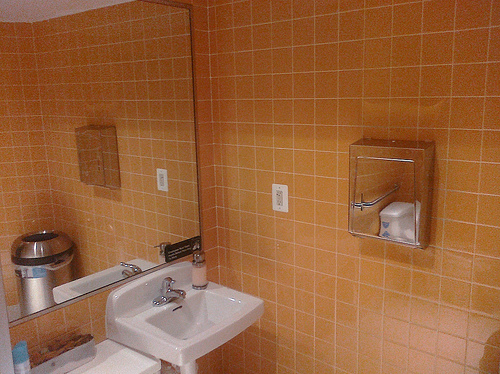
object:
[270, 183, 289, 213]
outlet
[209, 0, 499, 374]
wall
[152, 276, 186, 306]
faucet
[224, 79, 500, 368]
tile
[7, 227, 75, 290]
trash can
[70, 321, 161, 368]
umbrellas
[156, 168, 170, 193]
outlet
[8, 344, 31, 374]
can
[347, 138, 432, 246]
dispenser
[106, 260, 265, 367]
sink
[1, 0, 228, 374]
wall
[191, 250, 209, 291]
container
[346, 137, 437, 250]
container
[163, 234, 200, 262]
black sign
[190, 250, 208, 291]
soap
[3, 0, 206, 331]
mirror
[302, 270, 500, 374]
grout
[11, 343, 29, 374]
item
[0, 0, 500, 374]
toilet